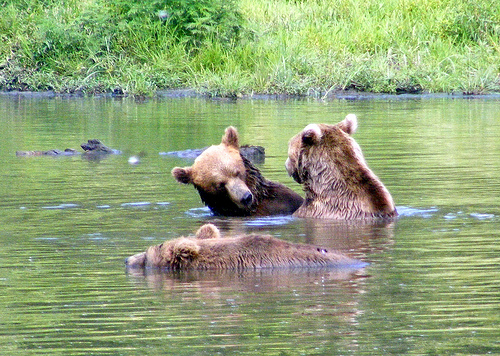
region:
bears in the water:
[91, 111, 423, 315]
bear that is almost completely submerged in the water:
[106, 210, 373, 287]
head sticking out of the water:
[278, 108, 391, 228]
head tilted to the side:
[169, 115, 269, 215]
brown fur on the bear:
[281, 98, 401, 234]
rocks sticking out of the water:
[14, 132, 112, 162]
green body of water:
[0, 89, 498, 354]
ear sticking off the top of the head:
[220, 120, 240, 150]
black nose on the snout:
[240, 190, 253, 203]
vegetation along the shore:
[1, 0, 498, 100]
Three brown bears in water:
[122, 113, 397, 276]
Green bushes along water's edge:
[5, 6, 252, 71]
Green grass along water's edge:
[1, 69, 497, 99]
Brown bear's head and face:
[170, 125, 254, 210]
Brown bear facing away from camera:
[283, 112, 366, 190]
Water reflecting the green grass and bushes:
[3, 92, 494, 352]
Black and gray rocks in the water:
[15, 138, 117, 161]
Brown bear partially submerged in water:
[123, 223, 364, 272]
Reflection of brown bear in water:
[299, 213, 395, 259]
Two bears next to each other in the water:
[168, 109, 398, 221]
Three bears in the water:
[96, 88, 427, 353]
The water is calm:
[25, 105, 130, 196]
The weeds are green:
[194, 21, 356, 81]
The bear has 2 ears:
[277, 93, 381, 176]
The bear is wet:
[222, 161, 324, 226]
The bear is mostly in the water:
[97, 230, 378, 295]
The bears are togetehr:
[162, 138, 422, 236]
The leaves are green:
[168, 5, 233, 72]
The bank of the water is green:
[156, 77, 496, 110]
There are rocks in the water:
[39, 127, 99, 208]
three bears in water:
[119, 134, 372, 296]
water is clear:
[325, 101, 417, 152]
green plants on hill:
[82, 0, 247, 67]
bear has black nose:
[228, 191, 270, 218]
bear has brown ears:
[169, 124, 259, 196]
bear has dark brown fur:
[215, 209, 309, 272]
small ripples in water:
[340, 214, 472, 335]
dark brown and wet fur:
[238, 162, 304, 225]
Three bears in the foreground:
[111, 103, 449, 291]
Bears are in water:
[112, 107, 412, 297]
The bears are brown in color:
[107, 99, 422, 309]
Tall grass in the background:
[1, 0, 496, 90]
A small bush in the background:
[105, 0, 250, 82]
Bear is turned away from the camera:
[272, 112, 417, 235]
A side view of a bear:
[110, 211, 380, 299]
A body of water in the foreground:
[0, 87, 497, 352]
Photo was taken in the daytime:
[0, 2, 496, 352]